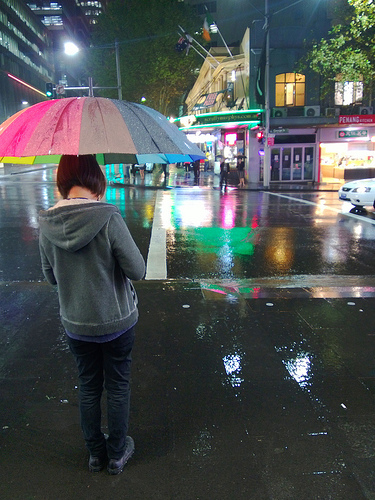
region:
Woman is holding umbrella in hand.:
[21, 55, 181, 377]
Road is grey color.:
[172, 359, 346, 462]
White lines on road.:
[140, 215, 369, 301]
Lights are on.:
[39, 23, 374, 192]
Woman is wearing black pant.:
[64, 335, 133, 450]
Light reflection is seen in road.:
[144, 174, 342, 404]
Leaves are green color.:
[327, 19, 374, 67]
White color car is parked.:
[335, 174, 373, 212]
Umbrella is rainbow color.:
[20, 109, 187, 162]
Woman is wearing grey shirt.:
[23, 201, 147, 350]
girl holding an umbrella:
[25, 81, 195, 319]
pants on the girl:
[59, 322, 154, 463]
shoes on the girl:
[77, 429, 148, 485]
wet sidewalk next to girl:
[214, 342, 322, 420]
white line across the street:
[143, 196, 190, 247]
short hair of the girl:
[47, 159, 117, 201]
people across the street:
[209, 135, 266, 200]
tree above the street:
[313, 16, 370, 88]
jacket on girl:
[29, 202, 142, 305]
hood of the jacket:
[39, 199, 110, 247]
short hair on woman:
[50, 159, 108, 199]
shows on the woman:
[84, 405, 153, 488]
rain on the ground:
[178, 365, 297, 457]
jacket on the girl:
[36, 205, 131, 306]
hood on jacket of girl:
[39, 197, 118, 245]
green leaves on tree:
[318, 27, 361, 74]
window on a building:
[264, 60, 328, 111]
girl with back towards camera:
[40, 140, 157, 268]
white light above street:
[54, 15, 107, 70]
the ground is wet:
[0, 166, 366, 493]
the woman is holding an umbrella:
[0, 81, 209, 491]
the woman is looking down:
[5, 135, 168, 308]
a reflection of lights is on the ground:
[199, 319, 353, 422]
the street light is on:
[53, 36, 137, 94]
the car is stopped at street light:
[336, 165, 374, 218]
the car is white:
[340, 155, 372, 221]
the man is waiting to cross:
[217, 151, 234, 195]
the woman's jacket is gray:
[30, 200, 145, 339]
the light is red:
[219, 131, 242, 151]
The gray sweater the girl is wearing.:
[26, 190, 149, 330]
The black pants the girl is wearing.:
[63, 332, 139, 453]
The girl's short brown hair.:
[51, 157, 107, 202]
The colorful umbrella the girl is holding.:
[7, 101, 198, 169]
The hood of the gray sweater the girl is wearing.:
[32, 206, 119, 256]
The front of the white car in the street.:
[333, 169, 373, 204]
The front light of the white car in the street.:
[351, 182, 372, 191]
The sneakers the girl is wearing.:
[71, 427, 134, 477]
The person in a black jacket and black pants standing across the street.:
[218, 155, 231, 187]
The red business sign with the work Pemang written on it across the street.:
[333, 116, 373, 126]